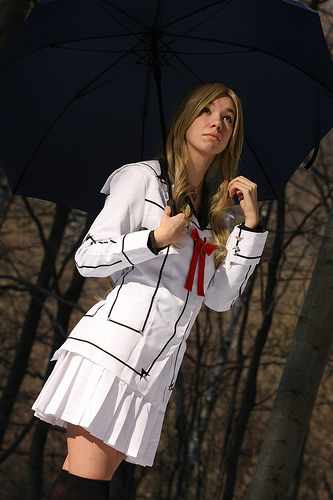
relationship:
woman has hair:
[34, 85, 267, 467] [164, 83, 244, 264]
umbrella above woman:
[10, 1, 332, 212] [34, 85, 267, 467]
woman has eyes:
[34, 85, 267, 467] [199, 104, 233, 123]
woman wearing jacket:
[34, 85, 267, 467] [74, 160, 271, 406]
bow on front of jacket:
[185, 228, 212, 295] [74, 160, 271, 406]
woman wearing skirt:
[34, 85, 267, 467] [39, 353, 167, 468]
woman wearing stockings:
[34, 85, 267, 467] [53, 470, 113, 499]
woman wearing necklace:
[34, 85, 267, 467] [178, 176, 205, 206]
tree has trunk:
[251, 163, 332, 467] [237, 212, 332, 499]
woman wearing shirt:
[34, 85, 267, 467] [240, 222, 265, 236]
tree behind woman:
[251, 163, 332, 467] [34, 85, 267, 467]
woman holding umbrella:
[34, 85, 267, 467] [10, 1, 332, 212]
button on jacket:
[233, 235, 243, 244] [74, 160, 271, 406]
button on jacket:
[233, 245, 243, 259] [74, 160, 271, 406]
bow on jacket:
[185, 228, 212, 295] [74, 160, 271, 406]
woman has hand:
[34, 85, 267, 467] [153, 206, 190, 249]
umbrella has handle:
[10, 1, 332, 212] [164, 197, 185, 232]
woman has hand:
[34, 85, 267, 467] [224, 172, 264, 220]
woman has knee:
[34, 85, 267, 467] [86, 489, 97, 499]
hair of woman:
[164, 83, 244, 264] [34, 85, 267, 467]